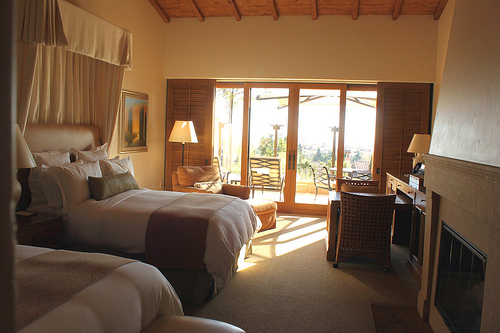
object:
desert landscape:
[117, 90, 150, 154]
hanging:
[118, 89, 149, 155]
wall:
[75, 2, 164, 188]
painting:
[116, 89, 151, 155]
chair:
[249, 156, 286, 201]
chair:
[172, 166, 278, 233]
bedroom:
[4, 0, 500, 331]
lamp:
[14, 114, 38, 220]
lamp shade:
[15, 121, 38, 171]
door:
[341, 93, 388, 200]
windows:
[211, 85, 379, 194]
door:
[245, 82, 291, 213]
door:
[290, 83, 345, 215]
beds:
[0, 122, 262, 332]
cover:
[68, 188, 263, 294]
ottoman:
[244, 198, 277, 231]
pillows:
[30, 141, 139, 215]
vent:
[430, 221, 489, 332]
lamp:
[167, 120, 199, 166]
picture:
[120, 88, 150, 153]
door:
[165, 77, 213, 188]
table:
[328, 188, 412, 247]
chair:
[332, 191, 398, 272]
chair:
[335, 178, 379, 192]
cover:
[7, 236, 180, 331]